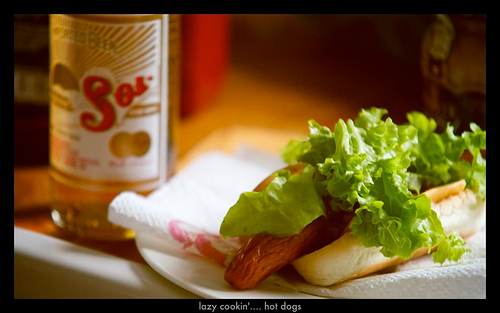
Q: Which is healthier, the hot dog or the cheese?
A: The cheese is healthier than the hot dog.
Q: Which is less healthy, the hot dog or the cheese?
A: The hot dog is less healthy than the cheese.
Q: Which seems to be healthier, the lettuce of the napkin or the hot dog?
A: The lettuce is healthier than the hot dog.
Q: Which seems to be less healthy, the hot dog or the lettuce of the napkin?
A: The hot dog is less healthy than the lettuce.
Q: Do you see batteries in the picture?
A: No, there are no batteries.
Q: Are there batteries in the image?
A: No, there are no batteries.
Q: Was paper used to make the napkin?
A: Yes, the napkin is made of paper.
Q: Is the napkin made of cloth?
A: No, the napkin is made of paper.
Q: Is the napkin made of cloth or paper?
A: The napkin is made of paper.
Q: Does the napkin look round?
A: Yes, the napkin is round.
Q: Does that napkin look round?
A: Yes, the napkin is round.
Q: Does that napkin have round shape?
A: Yes, the napkin is round.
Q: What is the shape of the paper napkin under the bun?
A: The napkin is round.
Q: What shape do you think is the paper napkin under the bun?
A: The napkin is round.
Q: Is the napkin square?
A: No, the napkin is round.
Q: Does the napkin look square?
A: No, the napkin is round.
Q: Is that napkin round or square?
A: The napkin is round.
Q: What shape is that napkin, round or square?
A: The napkin is round.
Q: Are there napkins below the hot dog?
A: Yes, there is a napkin below the hot dog.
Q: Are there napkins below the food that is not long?
A: Yes, there is a napkin below the hot dog.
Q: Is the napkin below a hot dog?
A: Yes, the napkin is below a hot dog.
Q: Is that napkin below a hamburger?
A: No, the napkin is below a hot dog.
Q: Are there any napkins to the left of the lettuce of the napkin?
A: Yes, there is a napkin to the left of the lettuce.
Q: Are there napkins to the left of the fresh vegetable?
A: Yes, there is a napkin to the left of the lettuce.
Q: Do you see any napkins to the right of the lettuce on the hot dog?
A: No, the napkin is to the left of the lettuce.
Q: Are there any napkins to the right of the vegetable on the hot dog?
A: No, the napkin is to the left of the lettuce.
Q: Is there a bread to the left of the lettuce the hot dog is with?
A: No, there is a napkin to the left of the lettuce.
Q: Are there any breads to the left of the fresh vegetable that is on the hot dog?
A: No, there is a napkin to the left of the lettuce.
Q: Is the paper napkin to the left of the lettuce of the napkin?
A: Yes, the napkin is to the left of the lettuce.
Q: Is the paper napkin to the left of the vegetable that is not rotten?
A: Yes, the napkin is to the left of the lettuce.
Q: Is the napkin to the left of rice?
A: No, the napkin is to the left of the lettuce.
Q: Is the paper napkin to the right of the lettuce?
A: No, the napkin is to the left of the lettuce.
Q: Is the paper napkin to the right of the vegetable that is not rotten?
A: No, the napkin is to the left of the lettuce.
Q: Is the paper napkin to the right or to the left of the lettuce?
A: The napkin is to the left of the lettuce.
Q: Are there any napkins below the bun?
A: Yes, there is a napkin below the bun.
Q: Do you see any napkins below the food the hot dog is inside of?
A: Yes, there is a napkin below the bun.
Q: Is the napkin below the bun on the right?
A: Yes, the napkin is below the bun.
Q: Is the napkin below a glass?
A: No, the napkin is below the bun.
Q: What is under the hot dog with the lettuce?
A: The napkin is under the hot dog.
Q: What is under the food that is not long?
A: The napkin is under the hot dog.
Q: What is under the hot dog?
A: The napkin is under the hot dog.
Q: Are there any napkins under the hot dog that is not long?
A: Yes, there is a napkin under the hot dog.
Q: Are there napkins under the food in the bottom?
A: Yes, there is a napkin under the hot dog.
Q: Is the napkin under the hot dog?
A: Yes, the napkin is under the hot dog.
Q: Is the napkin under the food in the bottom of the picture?
A: Yes, the napkin is under the hot dog.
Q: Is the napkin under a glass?
A: No, the napkin is under the hot dog.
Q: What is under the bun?
A: The napkin is under the bun.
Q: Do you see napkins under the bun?
A: Yes, there is a napkin under the bun.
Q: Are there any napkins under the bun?
A: Yes, there is a napkin under the bun.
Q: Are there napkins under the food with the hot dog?
A: Yes, there is a napkin under the bun.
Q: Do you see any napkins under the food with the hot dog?
A: Yes, there is a napkin under the bun.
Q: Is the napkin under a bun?
A: Yes, the napkin is under a bun.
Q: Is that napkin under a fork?
A: No, the napkin is under a bun.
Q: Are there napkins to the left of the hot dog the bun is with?
A: Yes, there is a napkin to the left of the hot dog.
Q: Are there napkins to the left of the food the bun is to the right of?
A: Yes, there is a napkin to the left of the hot dog.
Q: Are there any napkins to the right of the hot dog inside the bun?
A: No, the napkin is to the left of the hot dog.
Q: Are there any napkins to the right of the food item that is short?
A: No, the napkin is to the left of the hot dog.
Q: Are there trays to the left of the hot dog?
A: No, there is a napkin to the left of the hot dog.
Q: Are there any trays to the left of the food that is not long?
A: No, there is a napkin to the left of the hot dog.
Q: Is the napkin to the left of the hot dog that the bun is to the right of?
A: Yes, the napkin is to the left of the hot dog.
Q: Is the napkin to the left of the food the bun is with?
A: Yes, the napkin is to the left of the hot dog.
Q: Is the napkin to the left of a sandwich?
A: No, the napkin is to the left of the hot dog.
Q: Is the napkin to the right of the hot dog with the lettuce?
A: No, the napkin is to the left of the hot dog.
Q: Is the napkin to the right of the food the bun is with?
A: No, the napkin is to the left of the hot dog.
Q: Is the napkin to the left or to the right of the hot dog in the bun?
A: The napkin is to the left of the hot dog.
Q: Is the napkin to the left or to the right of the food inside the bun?
A: The napkin is to the left of the hot dog.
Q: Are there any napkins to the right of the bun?
A: No, the napkin is to the left of the bun.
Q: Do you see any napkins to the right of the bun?
A: No, the napkin is to the left of the bun.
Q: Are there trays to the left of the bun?
A: No, there is a napkin to the left of the bun.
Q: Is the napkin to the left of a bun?
A: Yes, the napkin is to the left of a bun.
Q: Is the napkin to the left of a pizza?
A: No, the napkin is to the left of a bun.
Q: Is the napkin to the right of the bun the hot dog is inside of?
A: No, the napkin is to the left of the bun.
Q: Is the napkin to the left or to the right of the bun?
A: The napkin is to the left of the bun.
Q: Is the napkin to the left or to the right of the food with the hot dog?
A: The napkin is to the left of the bun.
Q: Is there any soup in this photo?
A: No, there is no soup.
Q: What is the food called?
A: The food is a bun.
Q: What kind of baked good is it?
A: The food is a bun.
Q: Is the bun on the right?
A: Yes, the bun is on the right of the image.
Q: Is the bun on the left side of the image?
A: No, the bun is on the right of the image.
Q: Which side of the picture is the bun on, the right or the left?
A: The bun is on the right of the image.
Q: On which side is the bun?
A: The bun is on the right of the image.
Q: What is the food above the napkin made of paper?
A: The food is a bun.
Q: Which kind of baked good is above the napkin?
A: The food is a bun.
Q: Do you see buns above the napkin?
A: Yes, there is a bun above the napkin.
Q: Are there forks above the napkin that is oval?
A: No, there is a bun above the napkin.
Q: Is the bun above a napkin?
A: Yes, the bun is above a napkin.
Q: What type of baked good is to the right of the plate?
A: The food is a bun.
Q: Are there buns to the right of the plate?
A: Yes, there is a bun to the right of the plate.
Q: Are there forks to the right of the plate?
A: No, there is a bun to the right of the plate.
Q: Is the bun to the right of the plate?
A: Yes, the bun is to the right of the plate.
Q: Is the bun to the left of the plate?
A: No, the bun is to the right of the plate.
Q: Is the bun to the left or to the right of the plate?
A: The bun is to the right of the plate.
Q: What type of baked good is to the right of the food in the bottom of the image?
A: The food is a bun.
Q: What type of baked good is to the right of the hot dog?
A: The food is a bun.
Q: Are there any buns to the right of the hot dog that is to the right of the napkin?
A: Yes, there is a bun to the right of the hot dog.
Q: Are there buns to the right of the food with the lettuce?
A: Yes, there is a bun to the right of the hot dog.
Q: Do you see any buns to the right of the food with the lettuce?
A: Yes, there is a bun to the right of the hot dog.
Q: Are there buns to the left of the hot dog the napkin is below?
A: No, the bun is to the right of the hot dog.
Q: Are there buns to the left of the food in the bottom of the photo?
A: No, the bun is to the right of the hot dog.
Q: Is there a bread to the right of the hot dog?
A: No, there is a bun to the right of the hot dog.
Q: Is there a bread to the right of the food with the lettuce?
A: No, there is a bun to the right of the hot dog.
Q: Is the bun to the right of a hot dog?
A: Yes, the bun is to the right of a hot dog.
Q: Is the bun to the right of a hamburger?
A: No, the bun is to the right of a hot dog.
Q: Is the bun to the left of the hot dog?
A: No, the bun is to the right of the hot dog.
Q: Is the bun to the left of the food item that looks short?
A: No, the bun is to the right of the hot dog.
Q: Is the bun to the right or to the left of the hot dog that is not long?
A: The bun is to the right of the hot dog.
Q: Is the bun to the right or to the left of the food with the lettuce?
A: The bun is to the right of the hot dog.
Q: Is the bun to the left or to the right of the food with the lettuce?
A: The bun is to the right of the hot dog.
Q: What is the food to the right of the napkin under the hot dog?
A: The food is a bun.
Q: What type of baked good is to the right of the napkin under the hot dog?
A: The food is a bun.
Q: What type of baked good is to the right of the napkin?
A: The food is a bun.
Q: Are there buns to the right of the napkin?
A: Yes, there is a bun to the right of the napkin.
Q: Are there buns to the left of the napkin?
A: No, the bun is to the right of the napkin.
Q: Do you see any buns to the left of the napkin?
A: No, the bun is to the right of the napkin.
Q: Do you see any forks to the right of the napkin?
A: No, there is a bun to the right of the napkin.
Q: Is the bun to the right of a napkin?
A: Yes, the bun is to the right of a napkin.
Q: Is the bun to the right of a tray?
A: No, the bun is to the right of a napkin.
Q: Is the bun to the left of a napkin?
A: No, the bun is to the right of a napkin.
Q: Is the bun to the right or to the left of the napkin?
A: The bun is to the right of the napkin.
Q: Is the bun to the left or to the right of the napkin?
A: The bun is to the right of the napkin.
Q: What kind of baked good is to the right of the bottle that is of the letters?
A: The food is a bun.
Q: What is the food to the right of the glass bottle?
A: The food is a bun.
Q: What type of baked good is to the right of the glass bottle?
A: The food is a bun.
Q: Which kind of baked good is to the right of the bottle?
A: The food is a bun.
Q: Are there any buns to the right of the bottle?
A: Yes, there is a bun to the right of the bottle.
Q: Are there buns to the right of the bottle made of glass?
A: Yes, there is a bun to the right of the bottle.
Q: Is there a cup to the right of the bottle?
A: No, there is a bun to the right of the bottle.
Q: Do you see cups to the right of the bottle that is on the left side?
A: No, there is a bun to the right of the bottle.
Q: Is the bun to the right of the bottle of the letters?
A: Yes, the bun is to the right of the bottle.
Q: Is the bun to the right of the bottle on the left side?
A: Yes, the bun is to the right of the bottle.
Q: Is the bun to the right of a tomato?
A: No, the bun is to the right of the bottle.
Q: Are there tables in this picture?
A: Yes, there is a table.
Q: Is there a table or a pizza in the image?
A: Yes, there is a table.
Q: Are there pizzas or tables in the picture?
A: Yes, there is a table.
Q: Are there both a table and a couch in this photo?
A: No, there is a table but no couches.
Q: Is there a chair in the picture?
A: No, there are no chairs.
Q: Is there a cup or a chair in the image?
A: No, there are no chairs or cups.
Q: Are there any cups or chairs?
A: No, there are no chairs or cups.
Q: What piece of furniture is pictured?
A: The piece of furniture is a table.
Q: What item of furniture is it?
A: The piece of furniture is a table.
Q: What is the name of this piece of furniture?
A: That is a table.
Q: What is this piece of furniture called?
A: That is a table.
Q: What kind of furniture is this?
A: That is a table.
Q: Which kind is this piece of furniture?
A: That is a table.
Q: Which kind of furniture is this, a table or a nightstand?
A: That is a table.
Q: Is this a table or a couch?
A: This is a table.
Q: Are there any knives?
A: No, there are no knives.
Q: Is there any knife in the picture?
A: No, there are no knives.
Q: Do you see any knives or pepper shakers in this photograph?
A: No, there are no knives or pepper shakers.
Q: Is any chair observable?
A: No, there are no chairs.